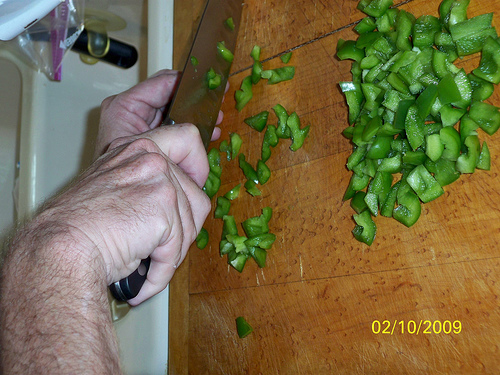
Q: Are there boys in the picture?
A: No, there are no boys.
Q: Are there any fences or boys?
A: No, there are no boys or fences.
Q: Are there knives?
A: Yes, there is a knife.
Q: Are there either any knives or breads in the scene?
A: Yes, there is a knife.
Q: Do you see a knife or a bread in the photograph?
A: Yes, there is a knife.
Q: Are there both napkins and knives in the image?
A: No, there is a knife but no napkins.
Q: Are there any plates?
A: No, there are no plates.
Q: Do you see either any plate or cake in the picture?
A: No, there are no plates or cakes.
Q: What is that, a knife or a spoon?
A: That is a knife.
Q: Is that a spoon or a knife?
A: That is a knife.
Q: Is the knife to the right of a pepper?
A: No, the knife is to the left of a pepper.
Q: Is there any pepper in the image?
A: Yes, there is a pepper.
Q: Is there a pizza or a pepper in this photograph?
A: Yes, there is a pepper.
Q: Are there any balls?
A: No, there are no balls.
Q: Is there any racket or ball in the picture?
A: No, there are no balls or rackets.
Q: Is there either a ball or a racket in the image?
A: No, there are no balls or rackets.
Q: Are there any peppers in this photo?
A: Yes, there are peppers.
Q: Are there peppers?
A: Yes, there are peppers.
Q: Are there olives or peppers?
A: Yes, there are peppers.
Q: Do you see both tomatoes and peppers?
A: No, there are peppers but no tomatoes.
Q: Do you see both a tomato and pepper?
A: No, there are peppers but no tomatoes.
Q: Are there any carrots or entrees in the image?
A: No, there are no carrots or entrees.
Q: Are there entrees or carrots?
A: No, there are no carrots or entrees.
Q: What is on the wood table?
A: The peppers are on the table.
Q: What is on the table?
A: The peppers are on the table.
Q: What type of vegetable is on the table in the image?
A: The vegetables are peppers.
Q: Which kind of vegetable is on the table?
A: The vegetables are peppers.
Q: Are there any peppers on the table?
A: Yes, there are peppers on the table.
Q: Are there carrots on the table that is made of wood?
A: No, there are peppers on the table.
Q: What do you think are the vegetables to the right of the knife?
A: The vegetables are peppers.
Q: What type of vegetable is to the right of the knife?
A: The vegetables are peppers.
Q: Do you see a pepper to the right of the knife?
A: Yes, there are peppers to the right of the knife.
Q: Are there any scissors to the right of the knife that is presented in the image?
A: No, there are peppers to the right of the knife.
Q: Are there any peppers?
A: Yes, there is a pepper.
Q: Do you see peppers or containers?
A: Yes, there is a pepper.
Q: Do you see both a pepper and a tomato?
A: No, there is a pepper but no tomatoes.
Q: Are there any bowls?
A: No, there are no bowls.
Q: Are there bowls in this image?
A: No, there are no bowls.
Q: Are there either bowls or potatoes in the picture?
A: No, there are no bowls or potatoes.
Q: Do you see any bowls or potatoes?
A: No, there are no bowls or potatoes.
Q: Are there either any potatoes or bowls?
A: No, there are no bowls or potatoes.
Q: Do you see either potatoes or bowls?
A: No, there are no bowls or potatoes.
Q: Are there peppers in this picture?
A: Yes, there is a pepper.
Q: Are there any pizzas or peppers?
A: Yes, there is a pepper.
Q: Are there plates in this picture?
A: No, there are no plates.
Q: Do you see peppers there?
A: Yes, there is a pepper.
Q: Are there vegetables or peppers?
A: Yes, there is a pepper.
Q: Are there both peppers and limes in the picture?
A: No, there is a pepper but no limes.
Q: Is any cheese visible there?
A: No, there is no cheese.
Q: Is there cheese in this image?
A: No, there is no cheese.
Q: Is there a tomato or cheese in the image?
A: No, there are no cheese or tomatoes.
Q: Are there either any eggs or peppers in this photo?
A: Yes, there is a pepper.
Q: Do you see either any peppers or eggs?
A: Yes, there is a pepper.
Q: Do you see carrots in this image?
A: No, there are no carrots.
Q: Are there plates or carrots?
A: No, there are no carrots or plates.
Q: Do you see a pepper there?
A: Yes, there is a pepper.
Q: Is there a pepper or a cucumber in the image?
A: Yes, there is a pepper.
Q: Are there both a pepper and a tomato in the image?
A: No, there is a pepper but no tomatoes.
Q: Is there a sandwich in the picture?
A: No, there are no sandwiches.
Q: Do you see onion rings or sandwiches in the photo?
A: No, there are no sandwiches or onion rings.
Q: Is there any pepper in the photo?
A: Yes, there is a pepper.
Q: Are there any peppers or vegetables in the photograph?
A: Yes, there is a pepper.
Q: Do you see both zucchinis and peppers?
A: No, there is a pepper but no zucchinis.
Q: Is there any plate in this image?
A: No, there are no plates.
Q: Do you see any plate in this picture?
A: No, there are no plates.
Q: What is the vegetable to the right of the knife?
A: The vegetable is a pepper.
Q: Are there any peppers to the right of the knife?
A: Yes, there is a pepper to the right of the knife.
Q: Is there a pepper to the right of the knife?
A: Yes, there is a pepper to the right of the knife.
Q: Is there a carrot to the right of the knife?
A: No, there is a pepper to the right of the knife.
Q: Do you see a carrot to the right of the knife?
A: No, there is a pepper to the right of the knife.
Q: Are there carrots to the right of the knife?
A: No, there is a pepper to the right of the knife.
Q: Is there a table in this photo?
A: Yes, there is a table.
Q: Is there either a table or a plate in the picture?
A: Yes, there is a table.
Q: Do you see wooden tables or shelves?
A: Yes, there is a wood table.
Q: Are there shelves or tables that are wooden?
A: Yes, the table is wooden.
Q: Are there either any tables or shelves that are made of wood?
A: Yes, the table is made of wood.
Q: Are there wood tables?
A: Yes, there is a wood table.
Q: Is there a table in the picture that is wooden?
A: Yes, there is a table that is wooden.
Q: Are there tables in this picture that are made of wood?
A: Yes, there is a table that is made of wood.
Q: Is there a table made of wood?
A: Yes, there is a table that is made of wood.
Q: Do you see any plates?
A: No, there are no plates.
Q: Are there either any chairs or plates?
A: No, there are no plates or chairs.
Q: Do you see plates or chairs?
A: No, there are no plates or chairs.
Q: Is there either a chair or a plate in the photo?
A: No, there are no plates or chairs.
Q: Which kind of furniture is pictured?
A: The furniture is a table.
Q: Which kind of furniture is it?
A: The piece of furniture is a table.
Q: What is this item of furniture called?
A: This is a table.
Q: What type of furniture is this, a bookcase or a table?
A: This is a table.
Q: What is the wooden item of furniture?
A: The piece of furniture is a table.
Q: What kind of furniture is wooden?
A: The furniture is a table.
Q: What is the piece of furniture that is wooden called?
A: The piece of furniture is a table.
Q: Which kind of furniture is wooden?
A: The furniture is a table.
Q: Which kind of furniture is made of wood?
A: The furniture is a table.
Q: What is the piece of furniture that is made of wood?
A: The piece of furniture is a table.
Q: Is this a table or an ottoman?
A: This is a table.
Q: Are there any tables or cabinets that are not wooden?
A: No, there is a table but it is wooden.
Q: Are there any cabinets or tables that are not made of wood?
A: No, there is a table but it is made of wood.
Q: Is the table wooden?
A: Yes, the table is wooden.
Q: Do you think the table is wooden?
A: Yes, the table is wooden.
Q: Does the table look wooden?
A: Yes, the table is wooden.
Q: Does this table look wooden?
A: Yes, the table is wooden.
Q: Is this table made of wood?
A: Yes, the table is made of wood.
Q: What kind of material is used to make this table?
A: The table is made of wood.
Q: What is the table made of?
A: The table is made of wood.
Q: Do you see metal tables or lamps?
A: No, there is a table but it is wooden.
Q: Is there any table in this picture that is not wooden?
A: No, there is a table but it is wooden.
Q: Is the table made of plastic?
A: No, the table is made of wood.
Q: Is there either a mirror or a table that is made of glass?
A: No, there is a table but it is made of wood.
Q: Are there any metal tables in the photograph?
A: No, there is a table but it is made of wood.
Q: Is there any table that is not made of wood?
A: No, there is a table but it is made of wood.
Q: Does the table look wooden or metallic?
A: The table is wooden.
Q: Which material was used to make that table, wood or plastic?
A: The table is made of wood.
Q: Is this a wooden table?
A: Yes, this is a wooden table.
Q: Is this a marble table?
A: No, this is a wooden table.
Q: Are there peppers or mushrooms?
A: Yes, there are peppers.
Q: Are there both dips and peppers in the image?
A: No, there are peppers but no dips.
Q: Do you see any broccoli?
A: No, there is no broccoli.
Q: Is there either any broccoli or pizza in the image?
A: No, there are no broccoli or pizzas.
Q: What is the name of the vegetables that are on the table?
A: The vegetables are peppers.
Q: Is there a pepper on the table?
A: Yes, there are peppers on the table.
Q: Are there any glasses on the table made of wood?
A: No, there are peppers on the table.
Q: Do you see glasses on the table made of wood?
A: No, there are peppers on the table.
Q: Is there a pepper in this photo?
A: Yes, there is a pepper.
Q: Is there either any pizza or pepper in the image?
A: Yes, there is a pepper.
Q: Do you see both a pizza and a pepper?
A: No, there is a pepper but no pizzas.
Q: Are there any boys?
A: No, there are no boys.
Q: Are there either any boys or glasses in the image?
A: No, there are no boys or glasses.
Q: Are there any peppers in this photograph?
A: Yes, there are peppers.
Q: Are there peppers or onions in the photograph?
A: Yes, there are peppers.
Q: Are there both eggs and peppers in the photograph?
A: No, there are peppers but no eggs.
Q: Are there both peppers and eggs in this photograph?
A: No, there are peppers but no eggs.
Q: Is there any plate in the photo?
A: No, there are no plates.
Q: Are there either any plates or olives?
A: No, there are no plates or olives.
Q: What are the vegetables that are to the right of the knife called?
A: The vegetables are peppers.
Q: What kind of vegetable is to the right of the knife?
A: The vegetables are peppers.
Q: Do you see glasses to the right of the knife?
A: No, there are peppers to the right of the knife.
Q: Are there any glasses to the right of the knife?
A: No, there are peppers to the right of the knife.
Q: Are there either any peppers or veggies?
A: Yes, there is a pepper.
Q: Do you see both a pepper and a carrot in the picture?
A: No, there is a pepper but no carrots.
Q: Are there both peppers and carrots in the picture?
A: No, there is a pepper but no carrots.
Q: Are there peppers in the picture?
A: Yes, there is a pepper.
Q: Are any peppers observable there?
A: Yes, there is a pepper.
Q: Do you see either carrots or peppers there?
A: Yes, there is a pepper.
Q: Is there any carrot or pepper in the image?
A: Yes, there is a pepper.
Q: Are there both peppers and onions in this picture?
A: No, there is a pepper but no onions.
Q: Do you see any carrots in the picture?
A: No, there are no carrots.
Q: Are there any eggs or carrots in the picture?
A: No, there are no carrots or eggs.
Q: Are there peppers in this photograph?
A: Yes, there is a pepper.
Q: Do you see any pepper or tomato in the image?
A: Yes, there is a pepper.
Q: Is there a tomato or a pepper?
A: Yes, there is a pepper.